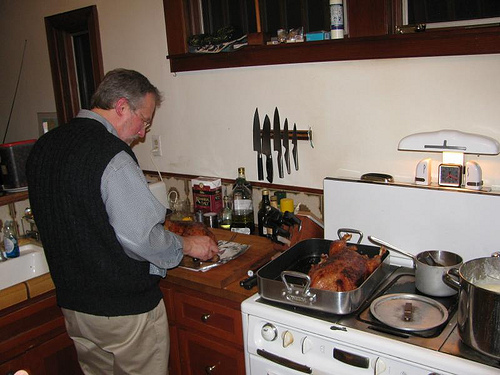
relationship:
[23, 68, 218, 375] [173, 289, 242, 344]
guy preparing drawer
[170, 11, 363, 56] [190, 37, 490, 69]
windows placed on sills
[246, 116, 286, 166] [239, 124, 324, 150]
knives arranged beside rack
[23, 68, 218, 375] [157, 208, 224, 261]
guy touching meat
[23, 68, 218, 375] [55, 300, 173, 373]
guy wearing pants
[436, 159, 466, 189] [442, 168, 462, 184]
clock with time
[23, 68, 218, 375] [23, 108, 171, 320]
guy wearing sweater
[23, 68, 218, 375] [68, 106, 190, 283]
guy wearing shirt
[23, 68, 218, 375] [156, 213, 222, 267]
guy making dinner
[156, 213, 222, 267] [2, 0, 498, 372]
dinner in kitchen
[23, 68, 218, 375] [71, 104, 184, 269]
guy turned of sleeves on shirt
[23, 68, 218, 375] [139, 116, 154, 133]
guy wears glasses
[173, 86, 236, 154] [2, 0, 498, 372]
wall in kitchen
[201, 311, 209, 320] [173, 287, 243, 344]
knob on drawer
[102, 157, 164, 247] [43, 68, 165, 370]
shirt on guy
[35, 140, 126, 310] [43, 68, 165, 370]
sweater on guy